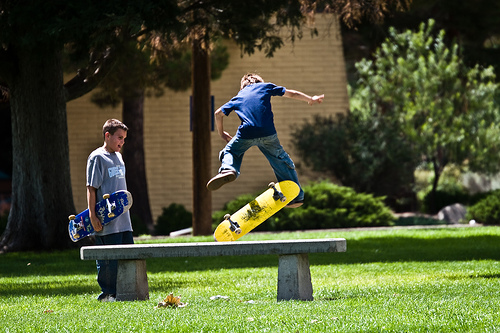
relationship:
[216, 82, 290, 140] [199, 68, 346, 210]
shirt of boy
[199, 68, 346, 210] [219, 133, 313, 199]
boy wearing jeans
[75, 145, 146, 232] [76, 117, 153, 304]
shirt of boy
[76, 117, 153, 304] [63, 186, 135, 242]
boy holding skateboard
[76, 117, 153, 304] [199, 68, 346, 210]
boy watching boy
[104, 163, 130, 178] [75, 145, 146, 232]
letters on shirt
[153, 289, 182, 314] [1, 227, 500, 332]
leaf on grass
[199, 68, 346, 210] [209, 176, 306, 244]
kid on skateboard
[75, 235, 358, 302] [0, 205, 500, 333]
bench in park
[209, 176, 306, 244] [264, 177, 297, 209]
skateboard has wheels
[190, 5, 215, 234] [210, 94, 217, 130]
pole with sign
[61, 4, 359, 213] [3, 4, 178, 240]
building by tree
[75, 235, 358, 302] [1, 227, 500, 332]
bench on grass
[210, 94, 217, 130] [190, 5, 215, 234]
sign on pole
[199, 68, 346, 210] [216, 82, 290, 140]
boy wearing shirt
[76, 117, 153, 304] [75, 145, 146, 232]
boy wearing shirt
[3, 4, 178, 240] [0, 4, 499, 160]
tree in background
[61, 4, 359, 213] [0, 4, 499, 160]
building in background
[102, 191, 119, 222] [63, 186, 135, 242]
wheels on skateboard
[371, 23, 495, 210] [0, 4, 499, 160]
tree in background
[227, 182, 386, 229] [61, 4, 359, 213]
bushes near building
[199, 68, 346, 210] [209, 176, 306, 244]
boy on skateboard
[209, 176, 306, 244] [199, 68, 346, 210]
skateboard of boy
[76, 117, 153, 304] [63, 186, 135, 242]
kid holding skateboard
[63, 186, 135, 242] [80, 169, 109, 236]
skateboard under arm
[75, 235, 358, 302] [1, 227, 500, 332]
bench in grass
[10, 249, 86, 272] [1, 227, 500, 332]
shadow on grass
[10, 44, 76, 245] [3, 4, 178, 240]
trunk of tree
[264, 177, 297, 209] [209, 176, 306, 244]
wheels on board